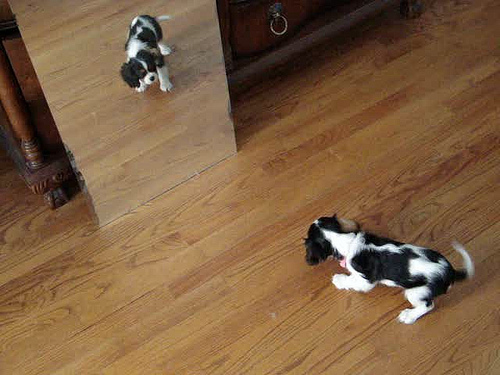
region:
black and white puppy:
[294, 207, 481, 339]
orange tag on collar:
[332, 250, 352, 273]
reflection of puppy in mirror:
[101, 5, 204, 112]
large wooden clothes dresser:
[4, 1, 492, 213]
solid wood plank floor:
[2, 1, 497, 372]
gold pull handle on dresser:
[259, 8, 297, 43]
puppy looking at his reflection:
[3, 2, 497, 372]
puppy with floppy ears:
[289, 190, 483, 342]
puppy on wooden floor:
[266, 146, 493, 373]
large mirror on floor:
[2, 2, 262, 237]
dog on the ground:
[290, 177, 441, 308]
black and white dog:
[252, 194, 479, 354]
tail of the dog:
[445, 226, 492, 286]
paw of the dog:
[313, 265, 362, 310]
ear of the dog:
[293, 236, 323, 268]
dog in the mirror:
[115, 15, 187, 92]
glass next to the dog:
[116, 140, 188, 214]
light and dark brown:
[31, 236, 158, 331]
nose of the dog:
[141, 70, 162, 92]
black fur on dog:
[374, 259, 401, 276]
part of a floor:
[218, 196, 256, 230]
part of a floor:
[230, 318, 281, 367]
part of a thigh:
[390, 280, 425, 314]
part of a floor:
[200, 299, 259, 363]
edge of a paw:
[388, 305, 423, 328]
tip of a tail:
[441, 232, 477, 273]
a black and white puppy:
[300, 196, 497, 328]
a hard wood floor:
[1, 171, 493, 372]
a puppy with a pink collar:
[303, 216, 355, 283]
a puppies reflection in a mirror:
[36, 12, 255, 222]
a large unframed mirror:
[3, 0, 247, 217]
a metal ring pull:
[264, 4, 296, 44]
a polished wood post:
[2, 80, 46, 183]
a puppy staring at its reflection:
[61, 17, 475, 332]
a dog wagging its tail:
[302, 206, 482, 330]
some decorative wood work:
[25, 170, 82, 202]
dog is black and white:
[285, 201, 495, 346]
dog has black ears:
[316, 216, 356, 278]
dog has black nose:
[145, 65, 161, 89]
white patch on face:
[141, 71, 181, 98]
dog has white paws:
[315, 266, 415, 321]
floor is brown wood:
[54, 179, 313, 344]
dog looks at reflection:
[41, 17, 254, 212]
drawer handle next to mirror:
[250, 21, 304, 55]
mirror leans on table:
[18, 30, 235, 179]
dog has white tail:
[150, 8, 171, 34]